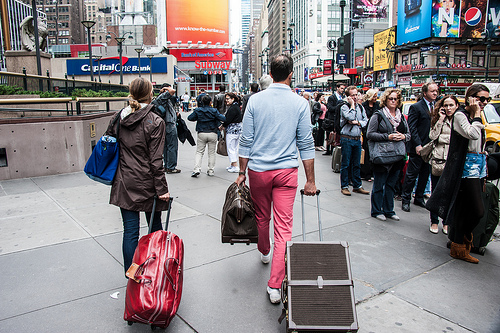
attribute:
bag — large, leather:
[225, 177, 296, 247]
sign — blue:
[58, 54, 169, 79]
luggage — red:
[123, 229, 198, 330]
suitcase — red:
[123, 227, 192, 330]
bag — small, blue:
[91, 133, 114, 188]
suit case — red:
[118, 202, 188, 316]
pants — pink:
[246, 167, 293, 209]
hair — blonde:
[127, 75, 153, 115]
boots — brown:
[447, 232, 479, 264]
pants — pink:
[243, 166, 300, 288]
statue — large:
[10, 8, 49, 61]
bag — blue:
[87, 125, 123, 187]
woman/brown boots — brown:
[444, 85, 489, 265]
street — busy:
[0, 112, 497, 332]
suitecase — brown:
[282, 239, 358, 331]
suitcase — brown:
[281, 190, 356, 331]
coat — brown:
[99, 91, 191, 198]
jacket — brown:
[104, 99, 234, 196]